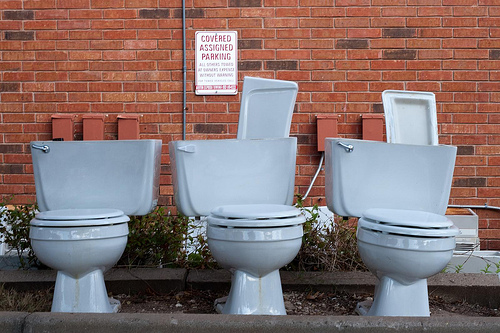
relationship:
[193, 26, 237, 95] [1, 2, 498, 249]
sign in brick building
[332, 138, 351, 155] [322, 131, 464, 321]
handle in toilet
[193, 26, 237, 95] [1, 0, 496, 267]
sign on building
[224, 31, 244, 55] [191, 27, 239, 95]
corner on sign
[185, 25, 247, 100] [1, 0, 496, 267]
sign hanging on building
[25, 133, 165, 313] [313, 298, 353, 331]
toilet on ground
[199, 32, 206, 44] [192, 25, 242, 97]
letters on sign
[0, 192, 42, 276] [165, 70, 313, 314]
weed next to toilet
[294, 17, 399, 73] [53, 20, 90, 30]
building made of brick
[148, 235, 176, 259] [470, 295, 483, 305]
leaves on ground